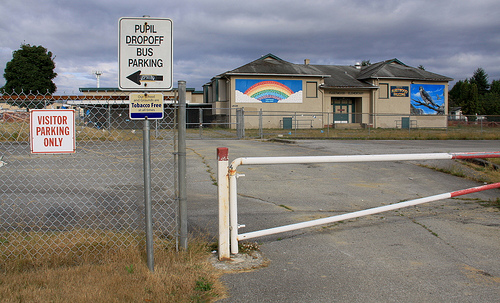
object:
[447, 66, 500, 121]
tree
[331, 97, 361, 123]
doorway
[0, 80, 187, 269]
fence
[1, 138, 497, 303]
concrete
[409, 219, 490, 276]
cracks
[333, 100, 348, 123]
door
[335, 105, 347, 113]
sign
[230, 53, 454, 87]
roof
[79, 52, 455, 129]
building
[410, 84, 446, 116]
mural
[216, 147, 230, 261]
pole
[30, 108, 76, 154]
sign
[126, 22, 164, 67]
text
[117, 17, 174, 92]
board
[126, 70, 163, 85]
black arrow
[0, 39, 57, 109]
tree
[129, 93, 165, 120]
sign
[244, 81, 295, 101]
rainbow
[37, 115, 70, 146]
text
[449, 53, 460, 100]
back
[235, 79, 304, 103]
mural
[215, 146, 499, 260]
fence